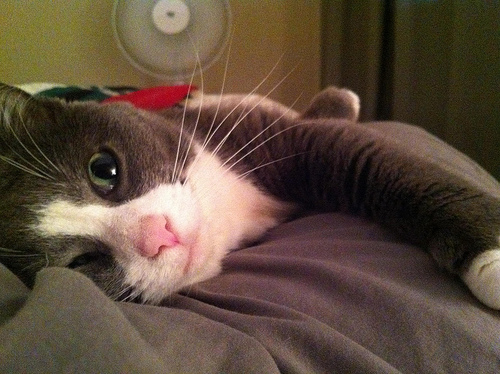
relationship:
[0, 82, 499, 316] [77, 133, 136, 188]
cat with eyes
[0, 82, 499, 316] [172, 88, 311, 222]
cat with hair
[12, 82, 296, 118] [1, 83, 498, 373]
pillow on bed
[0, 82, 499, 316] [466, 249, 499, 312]
cat with paw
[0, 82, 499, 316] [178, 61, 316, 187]
cat with whiskers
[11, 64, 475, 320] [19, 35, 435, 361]
cat on bed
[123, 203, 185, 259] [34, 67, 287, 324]
nose on cat's face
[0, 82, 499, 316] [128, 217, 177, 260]
cat with nose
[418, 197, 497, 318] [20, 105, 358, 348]
paw of cat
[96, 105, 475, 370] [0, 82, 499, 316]
blanket under cat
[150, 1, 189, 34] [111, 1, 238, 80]
white circle on fan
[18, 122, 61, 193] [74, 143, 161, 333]
whiskers above cat's eye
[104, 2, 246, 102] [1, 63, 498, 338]
fan behind cat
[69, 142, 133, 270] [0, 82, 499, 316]
cat's eye of cat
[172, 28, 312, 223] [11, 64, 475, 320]
hair on cat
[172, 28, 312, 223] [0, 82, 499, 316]
hair on cat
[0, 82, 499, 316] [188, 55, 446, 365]
cat on blanket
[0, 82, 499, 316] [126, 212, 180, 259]
cat has nose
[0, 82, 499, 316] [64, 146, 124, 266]
cat has eyes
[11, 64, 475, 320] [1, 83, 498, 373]
cat on bed